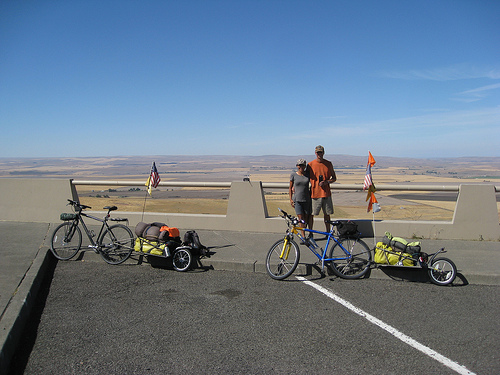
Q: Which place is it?
A: It is a parking lot.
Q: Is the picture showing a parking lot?
A: Yes, it is showing a parking lot.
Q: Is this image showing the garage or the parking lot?
A: It is showing the parking lot.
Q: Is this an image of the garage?
A: No, the picture is showing the parking lot.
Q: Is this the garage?
A: No, it is the parking lot.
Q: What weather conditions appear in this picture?
A: It is clear.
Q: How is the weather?
A: It is clear.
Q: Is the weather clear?
A: Yes, it is clear.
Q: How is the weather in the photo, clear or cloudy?
A: It is clear.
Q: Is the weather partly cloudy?
A: No, it is clear.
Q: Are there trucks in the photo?
A: No, there are no trucks.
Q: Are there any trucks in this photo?
A: No, there are no trucks.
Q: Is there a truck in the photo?
A: No, there are no trucks.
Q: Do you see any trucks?
A: No, there are no trucks.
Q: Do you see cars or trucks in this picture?
A: No, there are no trucks or cars.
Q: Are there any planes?
A: No, there are no planes.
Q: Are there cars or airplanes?
A: No, there are no airplanes or cars.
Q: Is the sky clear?
A: Yes, the sky is clear.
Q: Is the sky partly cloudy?
A: No, the sky is clear.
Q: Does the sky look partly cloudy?
A: No, the sky is clear.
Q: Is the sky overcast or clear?
A: The sky is clear.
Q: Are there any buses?
A: No, there are no buses.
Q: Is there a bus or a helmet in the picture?
A: No, there are no buses or helmets.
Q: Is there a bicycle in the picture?
A: Yes, there is a bicycle.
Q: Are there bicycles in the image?
A: Yes, there is a bicycle.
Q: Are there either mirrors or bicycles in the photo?
A: Yes, there is a bicycle.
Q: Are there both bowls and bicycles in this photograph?
A: No, there is a bicycle but no bowls.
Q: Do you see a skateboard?
A: No, there are no skateboards.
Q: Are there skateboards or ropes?
A: No, there are no skateboards or ropes.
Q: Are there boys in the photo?
A: No, there are no boys.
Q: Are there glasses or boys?
A: No, there are no boys or glasses.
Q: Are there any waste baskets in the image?
A: No, there are no waste baskets.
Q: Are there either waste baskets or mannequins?
A: No, there are no waste baskets or mannequins.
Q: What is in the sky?
A: The clouds are in the sky.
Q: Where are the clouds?
A: The clouds are in the sky.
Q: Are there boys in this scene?
A: No, there are no boys.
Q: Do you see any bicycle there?
A: Yes, there is a bicycle.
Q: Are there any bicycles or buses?
A: Yes, there is a bicycle.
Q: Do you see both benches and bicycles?
A: No, there is a bicycle but no benches.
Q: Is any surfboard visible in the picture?
A: No, there are no surfboards.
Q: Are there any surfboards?
A: No, there are no surfboards.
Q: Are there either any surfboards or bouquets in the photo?
A: No, there are no surfboards or bouquets.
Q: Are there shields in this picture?
A: No, there are no shields.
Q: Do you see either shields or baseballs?
A: No, there are no shields or baseballs.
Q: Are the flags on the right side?
A: Yes, the flags are on the right of the image.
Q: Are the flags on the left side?
A: No, the flags are on the right of the image.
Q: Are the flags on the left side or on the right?
A: The flags are on the right of the image.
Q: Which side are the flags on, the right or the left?
A: The flags are on the right of the image.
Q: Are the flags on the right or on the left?
A: The flags are on the right of the image.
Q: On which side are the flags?
A: The flags are on the right of the image.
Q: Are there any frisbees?
A: No, there are no frisbees.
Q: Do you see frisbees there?
A: No, there are no frisbees.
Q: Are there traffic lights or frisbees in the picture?
A: No, there are no frisbees or traffic lights.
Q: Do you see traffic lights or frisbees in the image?
A: No, there are no frisbees or traffic lights.